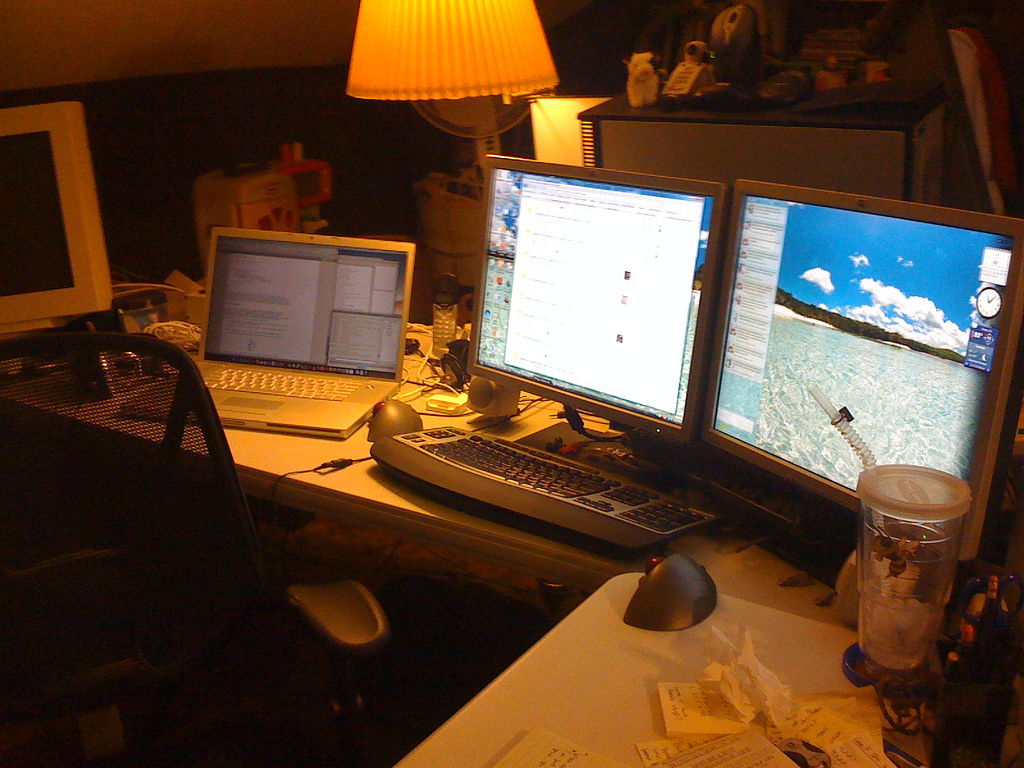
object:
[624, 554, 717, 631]
mouse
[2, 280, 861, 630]
desk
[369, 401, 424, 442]
mouse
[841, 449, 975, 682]
cup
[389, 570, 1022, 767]
desk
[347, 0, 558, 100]
shade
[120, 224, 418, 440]
laptop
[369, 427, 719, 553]
keyboard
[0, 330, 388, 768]
chair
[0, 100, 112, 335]
screen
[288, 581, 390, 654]
arm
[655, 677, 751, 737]
paper